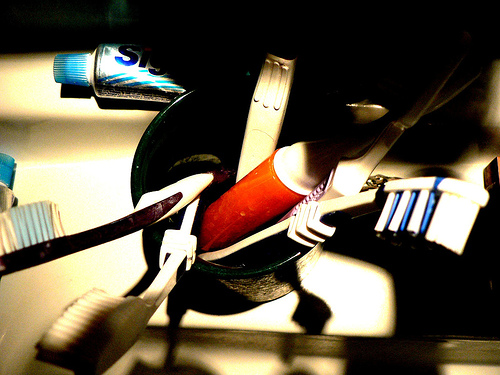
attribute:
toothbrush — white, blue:
[287, 177, 489, 255]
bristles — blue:
[373, 191, 479, 256]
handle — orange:
[201, 139, 306, 255]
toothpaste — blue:
[53, 43, 183, 103]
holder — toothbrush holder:
[131, 80, 337, 303]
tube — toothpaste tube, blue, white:
[53, 42, 186, 103]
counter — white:
[0, 54, 499, 372]